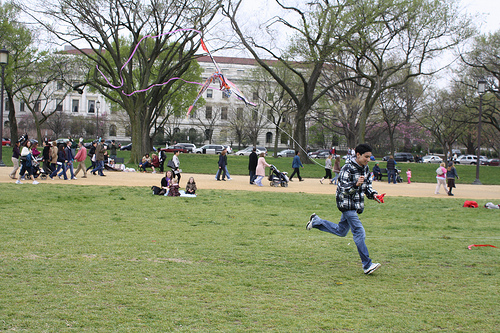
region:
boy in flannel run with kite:
[337, 148, 377, 270]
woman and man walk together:
[249, 147, 267, 187]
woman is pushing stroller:
[266, 165, 288, 186]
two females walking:
[436, 160, 456, 197]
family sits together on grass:
[157, 170, 199, 197]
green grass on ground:
[4, 195, 299, 331]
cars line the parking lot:
[151, 136, 493, 155]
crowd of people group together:
[9, 137, 92, 183]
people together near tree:
[141, 145, 166, 172]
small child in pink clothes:
[405, 167, 415, 184]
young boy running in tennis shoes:
[305, 141, 383, 275]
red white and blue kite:
[93, 26, 258, 116]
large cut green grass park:
[2, 182, 497, 331]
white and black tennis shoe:
[363, 261, 381, 275]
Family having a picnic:
[151, 168, 196, 198]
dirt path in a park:
[1, 165, 499, 200]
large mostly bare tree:
[219, 1, 421, 163]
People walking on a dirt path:
[9, 139, 106, 183]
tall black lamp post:
[93, 100, 101, 135]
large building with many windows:
[4, 45, 362, 156]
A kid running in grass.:
[303, 141, 387, 274]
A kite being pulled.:
[95, 29, 260, 119]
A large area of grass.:
[0, 183, 499, 331]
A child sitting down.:
[184, 175, 199, 195]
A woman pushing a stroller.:
[253, 150, 291, 187]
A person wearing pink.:
[435, 161, 447, 196]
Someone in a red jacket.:
[71, 138, 89, 177]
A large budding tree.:
[221, 0, 413, 164]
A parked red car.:
[158, 142, 192, 154]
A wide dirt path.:
[371, 180, 498, 200]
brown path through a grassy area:
[0, 141, 496, 329]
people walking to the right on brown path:
[0, 120, 497, 185]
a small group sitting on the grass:
[150, 165, 197, 201]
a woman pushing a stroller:
[250, 150, 290, 185]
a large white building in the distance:
[0, 45, 375, 150]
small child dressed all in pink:
[404, 167, 413, 182]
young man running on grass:
[304, 140, 386, 298]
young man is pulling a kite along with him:
[94, 27, 384, 202]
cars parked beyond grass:
[1, 133, 496, 165]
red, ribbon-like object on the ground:
[465, 240, 499, 254]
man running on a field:
[297, 149, 397, 283]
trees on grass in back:
[260, 2, 391, 140]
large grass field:
[64, 221, 274, 332]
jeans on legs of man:
[318, 216, 369, 266]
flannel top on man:
[322, 161, 379, 212]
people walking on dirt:
[4, 131, 108, 181]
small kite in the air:
[207, 18, 261, 65]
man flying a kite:
[305, 131, 399, 288]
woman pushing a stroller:
[250, 151, 270, 176]